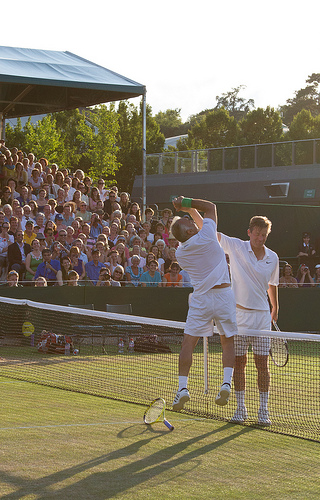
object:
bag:
[36, 329, 79, 355]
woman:
[125, 254, 144, 288]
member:
[110, 242, 162, 286]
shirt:
[158, 258, 166, 271]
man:
[171, 197, 279, 426]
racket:
[269, 318, 289, 367]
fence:
[278, 386, 288, 393]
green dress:
[25, 251, 43, 281]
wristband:
[181, 197, 193, 208]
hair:
[249, 215, 273, 236]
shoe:
[172, 386, 191, 410]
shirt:
[84, 259, 106, 286]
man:
[84, 248, 106, 286]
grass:
[1, 341, 317, 497]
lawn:
[0, 345, 141, 484]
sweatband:
[181, 197, 193, 208]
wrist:
[183, 198, 195, 209]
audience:
[0, 138, 320, 287]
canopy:
[0, 44, 147, 120]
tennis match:
[0, 195, 320, 500]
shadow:
[0, 421, 267, 500]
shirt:
[219, 232, 279, 311]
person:
[82, 222, 93, 238]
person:
[24, 239, 45, 281]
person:
[75, 200, 92, 222]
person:
[110, 264, 124, 286]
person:
[139, 259, 163, 288]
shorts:
[234, 307, 272, 356]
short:
[184, 286, 239, 339]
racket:
[143, 396, 175, 431]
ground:
[1, 336, 318, 498]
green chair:
[102, 304, 142, 355]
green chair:
[68, 303, 103, 353]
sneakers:
[234, 390, 270, 409]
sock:
[178, 376, 188, 392]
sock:
[223, 366, 235, 383]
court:
[0, 286, 319, 500]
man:
[170, 195, 239, 411]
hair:
[131, 254, 141, 265]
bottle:
[118, 338, 125, 354]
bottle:
[128, 338, 135, 353]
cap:
[120, 338, 122, 340]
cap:
[131, 338, 134, 340]